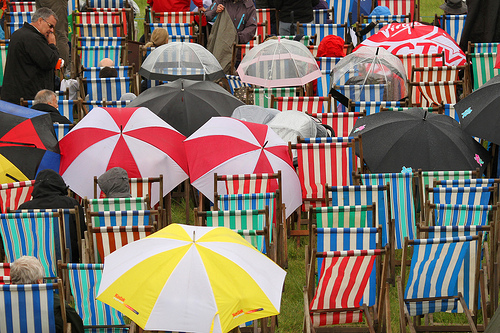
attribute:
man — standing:
[4, 8, 64, 102]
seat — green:
[309, 203, 383, 234]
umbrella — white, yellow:
[96, 218, 292, 333]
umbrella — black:
[350, 107, 493, 176]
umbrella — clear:
[236, 34, 326, 91]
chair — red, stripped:
[284, 142, 354, 209]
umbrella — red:
[59, 106, 190, 210]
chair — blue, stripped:
[400, 234, 488, 333]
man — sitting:
[7, 253, 92, 331]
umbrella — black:
[137, 41, 230, 86]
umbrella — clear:
[326, 45, 417, 109]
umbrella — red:
[184, 115, 306, 220]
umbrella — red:
[352, 19, 475, 68]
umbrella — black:
[0, 100, 63, 192]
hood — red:
[316, 34, 349, 59]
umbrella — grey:
[123, 77, 247, 138]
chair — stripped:
[307, 204, 378, 285]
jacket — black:
[22, 168, 88, 265]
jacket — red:
[313, 33, 350, 58]